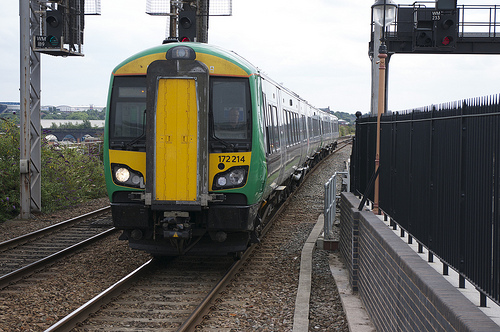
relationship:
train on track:
[101, 43, 340, 264] [39, 241, 257, 330]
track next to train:
[4, 207, 259, 330] [98, 33, 355, 248]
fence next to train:
[350, 92, 499, 309] [101, 43, 340, 264]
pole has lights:
[365, 0, 387, 213] [370, 0, 395, 30]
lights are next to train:
[370, 0, 395, 30] [101, 43, 340, 264]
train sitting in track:
[101, 43, 340, 264] [37, 255, 248, 330]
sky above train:
[0, 5, 493, 123] [93, 45, 355, 280]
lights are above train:
[143, 0, 233, 17] [101, 43, 340, 264]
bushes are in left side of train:
[0, 115, 107, 220] [101, 43, 340, 264]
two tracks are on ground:
[0, 252, 237, 329] [6, 215, 336, 327]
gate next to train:
[299, 166, 356, 253] [98, 34, 368, 265]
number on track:
[216, 153, 246, 163] [0, 136, 352, 328]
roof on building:
[37, 117, 106, 129] [38, 117, 105, 142]